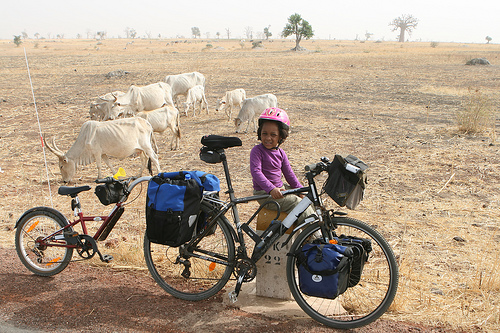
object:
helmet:
[257, 106, 291, 133]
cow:
[232, 93, 278, 133]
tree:
[280, 12, 315, 51]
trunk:
[291, 44, 306, 52]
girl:
[248, 107, 329, 248]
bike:
[13, 134, 399, 330]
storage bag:
[145, 170, 221, 248]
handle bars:
[304, 163, 317, 171]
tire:
[285, 217, 400, 328]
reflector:
[325, 237, 341, 245]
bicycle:
[143, 134, 399, 329]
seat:
[201, 134, 243, 149]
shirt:
[250, 143, 304, 195]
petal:
[228, 290, 238, 303]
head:
[257, 119, 287, 149]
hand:
[270, 187, 286, 199]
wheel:
[14, 206, 75, 276]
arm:
[250, 146, 276, 192]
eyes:
[262, 133, 277, 136]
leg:
[253, 184, 322, 247]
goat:
[182, 84, 209, 116]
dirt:
[1, 240, 498, 333]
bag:
[295, 237, 353, 300]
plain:
[0, 38, 499, 222]